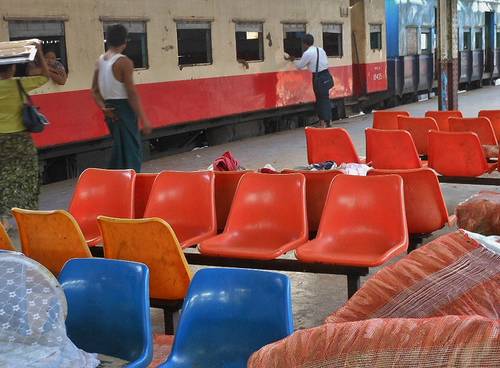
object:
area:
[0, 110, 500, 367]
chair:
[58, 258, 154, 368]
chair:
[10, 206, 96, 278]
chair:
[69, 167, 137, 245]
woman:
[1, 44, 50, 242]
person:
[23, 48, 68, 85]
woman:
[293, 32, 338, 127]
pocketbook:
[313, 47, 334, 93]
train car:
[0, 0, 389, 150]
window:
[7, 20, 71, 80]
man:
[291, 33, 335, 128]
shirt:
[294, 44, 328, 72]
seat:
[97, 214, 193, 300]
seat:
[11, 207, 93, 275]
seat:
[1, 222, 17, 251]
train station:
[0, 0, 500, 368]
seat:
[69, 168, 137, 245]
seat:
[143, 171, 219, 250]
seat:
[196, 171, 308, 261]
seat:
[295, 174, 412, 269]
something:
[0, 39, 45, 64]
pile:
[206, 150, 248, 171]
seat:
[158, 266, 295, 367]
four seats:
[68, 167, 410, 266]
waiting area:
[1, 111, 498, 366]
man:
[92, 23, 153, 173]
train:
[2, 1, 499, 187]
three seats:
[0, 206, 194, 301]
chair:
[1, 223, 13, 253]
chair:
[97, 214, 198, 300]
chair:
[364, 127, 422, 170]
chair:
[428, 129, 499, 176]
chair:
[160, 268, 292, 368]